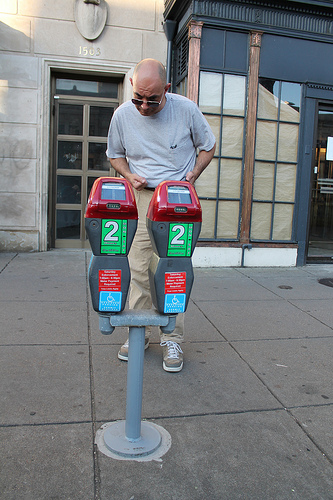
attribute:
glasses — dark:
[129, 87, 166, 109]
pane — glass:
[54, 101, 89, 136]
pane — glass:
[82, 104, 113, 141]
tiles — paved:
[195, 294, 320, 349]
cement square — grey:
[2, 263, 87, 304]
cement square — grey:
[0, 343, 91, 423]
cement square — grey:
[97, 411, 331, 498]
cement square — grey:
[192, 267, 281, 301]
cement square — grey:
[231, 335, 332, 412]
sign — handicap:
[163, 292, 184, 313]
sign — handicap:
[97, 288, 122, 312]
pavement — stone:
[3, 249, 332, 498]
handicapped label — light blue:
[160, 293, 187, 314]